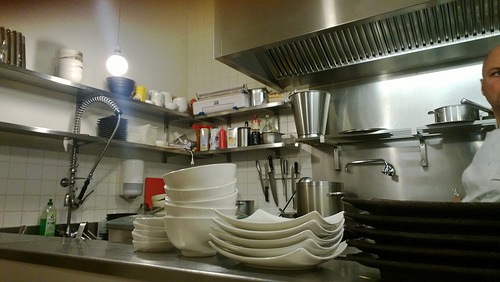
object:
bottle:
[214, 127, 227, 150]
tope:
[45, 199, 54, 206]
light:
[103, 54, 129, 77]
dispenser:
[118, 158, 144, 201]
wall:
[0, 0, 194, 227]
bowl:
[158, 163, 236, 190]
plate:
[209, 216, 347, 240]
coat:
[457, 128, 497, 204]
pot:
[280, 88, 331, 143]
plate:
[338, 195, 500, 219]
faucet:
[67, 190, 96, 210]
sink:
[28, 221, 111, 240]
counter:
[0, 232, 382, 282]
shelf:
[0, 121, 213, 163]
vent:
[259, 0, 499, 81]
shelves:
[0, 62, 193, 121]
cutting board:
[144, 177, 164, 210]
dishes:
[206, 208, 343, 230]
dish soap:
[36, 198, 58, 238]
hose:
[67, 95, 122, 168]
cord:
[111, 0, 123, 48]